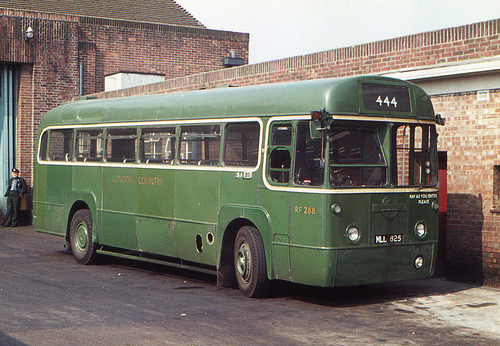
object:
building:
[1, 0, 500, 289]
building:
[69, 18, 499, 295]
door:
[407, 151, 447, 278]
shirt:
[11, 178, 17, 192]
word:
[294, 206, 316, 215]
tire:
[233, 223, 275, 299]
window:
[266, 146, 291, 187]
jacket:
[2, 176, 27, 197]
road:
[1, 220, 500, 345]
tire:
[70, 208, 103, 266]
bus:
[30, 75, 445, 299]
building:
[0, 0, 250, 215]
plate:
[375, 234, 404, 243]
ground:
[418, 47, 450, 109]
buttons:
[33, 75, 448, 301]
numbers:
[376, 95, 398, 108]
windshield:
[322, 118, 440, 190]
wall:
[66, 21, 499, 292]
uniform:
[4, 177, 27, 226]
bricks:
[0, 9, 499, 289]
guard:
[4, 168, 28, 227]